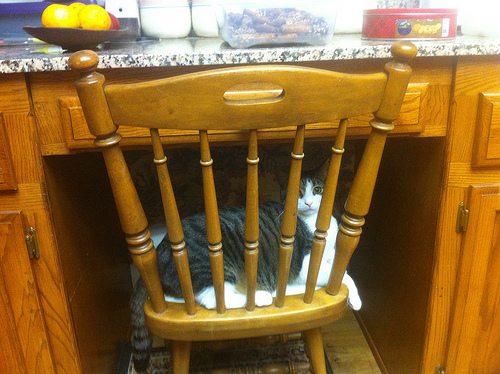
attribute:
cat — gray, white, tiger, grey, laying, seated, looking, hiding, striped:
[118, 154, 363, 373]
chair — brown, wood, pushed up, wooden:
[68, 38, 418, 374]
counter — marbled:
[1, 5, 500, 74]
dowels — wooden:
[67, 40, 419, 314]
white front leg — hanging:
[337, 269, 364, 313]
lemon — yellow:
[78, 4, 113, 32]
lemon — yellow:
[43, 1, 80, 27]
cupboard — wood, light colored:
[1, 72, 82, 373]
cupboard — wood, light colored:
[415, 55, 500, 373]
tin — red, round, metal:
[360, 7, 459, 42]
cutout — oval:
[221, 80, 286, 108]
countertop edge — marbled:
[0, 40, 499, 72]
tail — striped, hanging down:
[127, 275, 150, 374]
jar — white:
[141, 0, 192, 39]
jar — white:
[190, 2, 218, 38]